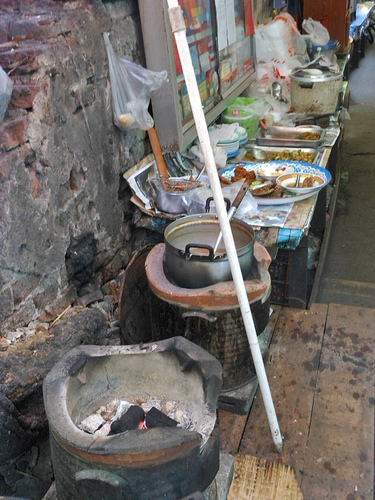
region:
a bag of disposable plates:
[247, 15, 311, 66]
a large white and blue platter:
[223, 158, 331, 207]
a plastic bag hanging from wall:
[101, 31, 168, 131]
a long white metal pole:
[164, 0, 284, 452]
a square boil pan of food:
[256, 119, 324, 145]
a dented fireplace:
[38, 340, 235, 496]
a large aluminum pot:
[295, 60, 344, 114]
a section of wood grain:
[229, 452, 300, 495]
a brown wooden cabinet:
[299, 2, 351, 48]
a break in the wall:
[62, 232, 115, 313]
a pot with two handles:
[160, 195, 255, 287]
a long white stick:
[166, 0, 286, 451]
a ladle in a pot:
[210, 171, 258, 255]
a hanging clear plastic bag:
[95, 31, 167, 131]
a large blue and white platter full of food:
[217, 159, 331, 204]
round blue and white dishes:
[206, 123, 247, 159]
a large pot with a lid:
[287, 68, 341, 115]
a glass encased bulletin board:
[137, 0, 254, 156]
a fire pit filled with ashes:
[40, 334, 223, 497]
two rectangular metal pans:
[238, 124, 322, 163]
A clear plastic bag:
[101, 31, 167, 128]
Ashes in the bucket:
[80, 398, 191, 439]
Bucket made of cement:
[42, 335, 219, 497]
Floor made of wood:
[216, 302, 371, 499]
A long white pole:
[166, 0, 283, 450]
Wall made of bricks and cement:
[1, 1, 140, 497]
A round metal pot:
[163, 196, 252, 287]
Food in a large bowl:
[218, 160, 329, 203]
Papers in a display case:
[170, 0, 254, 132]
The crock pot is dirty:
[290, 68, 338, 113]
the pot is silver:
[147, 196, 273, 293]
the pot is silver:
[162, 215, 241, 271]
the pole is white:
[172, 50, 301, 451]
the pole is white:
[216, 235, 289, 490]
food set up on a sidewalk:
[131, 11, 356, 250]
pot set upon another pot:
[155, 191, 260, 288]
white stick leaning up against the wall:
[162, 1, 287, 460]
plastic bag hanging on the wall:
[98, 24, 167, 133]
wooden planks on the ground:
[106, 276, 373, 498]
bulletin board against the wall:
[158, 0, 287, 135]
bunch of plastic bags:
[253, 12, 331, 123]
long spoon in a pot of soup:
[214, 175, 252, 262]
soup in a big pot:
[185, 243, 230, 254]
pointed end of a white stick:
[268, 435, 290, 456]